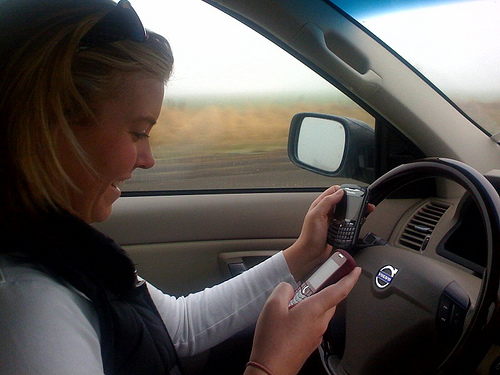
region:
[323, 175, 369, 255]
The black cell phone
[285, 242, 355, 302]
The red cell phone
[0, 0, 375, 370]
The woman holding the cell phones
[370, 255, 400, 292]
The volvo logo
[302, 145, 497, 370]
The car's steering wheel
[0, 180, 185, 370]
The scarf worn by the woman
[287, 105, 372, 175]
The side mirror of the car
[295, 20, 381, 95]
The driver's side hand hold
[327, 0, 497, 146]
The windshield glass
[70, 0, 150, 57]
The sunglasses on the woman's head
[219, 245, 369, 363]
the girl is on the phone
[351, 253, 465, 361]
the car is on the steering wheel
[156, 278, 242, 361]
the woman is wearing long sleeves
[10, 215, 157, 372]
the girl is wearing a black vest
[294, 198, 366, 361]
the girl has two phones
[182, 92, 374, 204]
dead grass is outside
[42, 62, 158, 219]
the girl is smiling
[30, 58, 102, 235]
the girl has light hair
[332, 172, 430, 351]
the phone is black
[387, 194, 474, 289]
the air vent is open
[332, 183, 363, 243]
a blackberry phone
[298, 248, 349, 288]
a cellphone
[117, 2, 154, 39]
sunglasses in hair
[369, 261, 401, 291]
logo on the steering wheel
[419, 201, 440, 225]
vent on the car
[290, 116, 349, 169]
the mirror on the outside of car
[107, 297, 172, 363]
a black vest the women is wearing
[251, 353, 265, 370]
a hair tie on right wrist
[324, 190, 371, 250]
women is holding a cellphone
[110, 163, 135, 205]
the women is smiling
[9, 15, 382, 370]
this is a woman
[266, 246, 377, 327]
this is a phone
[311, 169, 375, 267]
this is a phone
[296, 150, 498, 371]
this is a steering wheel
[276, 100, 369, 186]
this is a side mirror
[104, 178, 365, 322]
this is a hand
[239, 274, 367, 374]
this is a hand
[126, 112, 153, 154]
the eye of a lady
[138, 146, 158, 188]
the nose of a lady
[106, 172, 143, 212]
the mouth of a lady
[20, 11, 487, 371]
woman sitting in car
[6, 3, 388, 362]
woman holding two cell phones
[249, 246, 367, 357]
woman holding red cell phone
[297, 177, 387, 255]
woman holding black cell phone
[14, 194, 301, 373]
woman wearing white shirt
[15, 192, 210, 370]
woman wearing black vest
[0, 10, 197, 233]
woman with blonde hair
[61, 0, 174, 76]
woman with sunglasses on head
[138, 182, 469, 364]
brown inside of car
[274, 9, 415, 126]
tan door handle